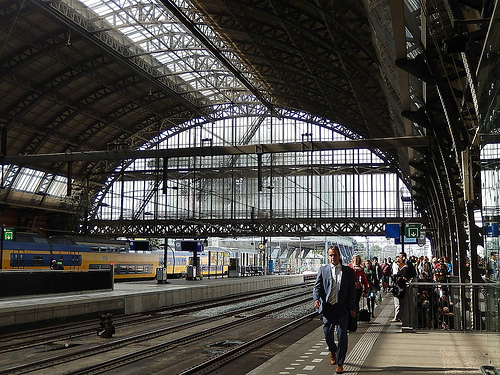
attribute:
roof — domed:
[62, 3, 404, 115]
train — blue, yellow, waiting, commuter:
[10, 247, 278, 276]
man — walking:
[312, 247, 361, 363]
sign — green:
[404, 224, 423, 240]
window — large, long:
[32, 255, 44, 265]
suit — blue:
[307, 264, 351, 323]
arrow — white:
[409, 230, 420, 238]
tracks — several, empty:
[139, 334, 231, 366]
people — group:
[341, 280, 468, 330]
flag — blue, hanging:
[382, 222, 400, 243]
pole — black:
[402, 219, 408, 254]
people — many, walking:
[334, 244, 445, 308]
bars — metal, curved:
[161, 117, 363, 152]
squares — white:
[301, 355, 322, 370]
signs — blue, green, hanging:
[378, 219, 428, 244]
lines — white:
[291, 355, 312, 361]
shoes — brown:
[325, 352, 348, 373]